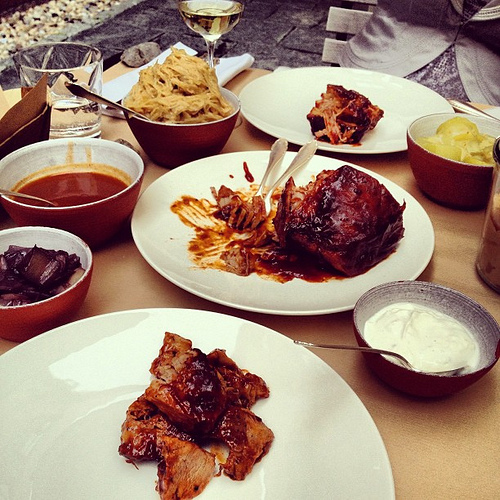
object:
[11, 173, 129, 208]
soup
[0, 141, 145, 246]
bowl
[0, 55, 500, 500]
table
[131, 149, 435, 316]
plate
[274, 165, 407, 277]
food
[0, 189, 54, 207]
spoon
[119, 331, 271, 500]
meat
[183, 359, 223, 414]
sauce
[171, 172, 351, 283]
sauce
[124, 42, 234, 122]
puree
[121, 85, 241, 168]
bowl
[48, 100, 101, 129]
water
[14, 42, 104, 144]
glass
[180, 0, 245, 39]
wine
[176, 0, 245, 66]
stemmed glass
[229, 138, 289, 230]
fork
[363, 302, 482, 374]
cream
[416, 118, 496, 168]
pickles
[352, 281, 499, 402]
bowl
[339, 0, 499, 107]
person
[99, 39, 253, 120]
napkin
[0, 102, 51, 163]
napkin holder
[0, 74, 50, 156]
napkin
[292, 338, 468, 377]
spoon